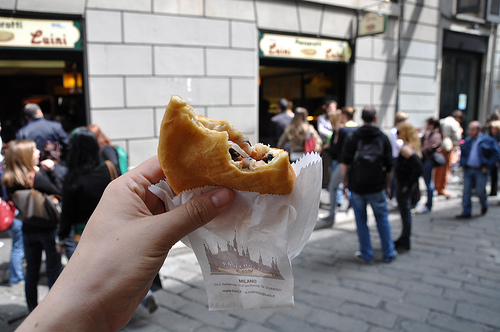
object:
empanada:
[157, 94, 298, 195]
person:
[11, 154, 237, 332]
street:
[0, 203, 500, 332]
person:
[453, 120, 499, 220]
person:
[319, 106, 362, 222]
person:
[54, 126, 122, 262]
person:
[410, 116, 445, 215]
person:
[434, 111, 464, 197]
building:
[0, 0, 500, 188]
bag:
[146, 150, 324, 310]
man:
[338, 105, 398, 264]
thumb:
[146, 187, 235, 241]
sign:
[357, 10, 388, 38]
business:
[258, 34, 358, 188]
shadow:
[372, 0, 423, 129]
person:
[270, 97, 296, 130]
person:
[276, 107, 324, 164]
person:
[15, 102, 71, 163]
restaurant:
[0, 10, 88, 143]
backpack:
[352, 130, 385, 172]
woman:
[391, 123, 425, 255]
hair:
[397, 123, 425, 159]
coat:
[458, 136, 500, 169]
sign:
[257, 32, 354, 65]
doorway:
[260, 57, 349, 189]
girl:
[0, 138, 63, 314]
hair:
[4, 139, 39, 188]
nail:
[211, 188, 232, 209]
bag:
[303, 134, 317, 154]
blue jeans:
[347, 189, 395, 264]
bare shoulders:
[400, 143, 414, 158]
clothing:
[393, 153, 423, 188]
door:
[436, 25, 492, 130]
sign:
[457, 93, 467, 111]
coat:
[13, 115, 69, 160]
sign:
[0, 15, 83, 50]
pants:
[435, 145, 451, 196]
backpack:
[114, 147, 128, 175]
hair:
[63, 127, 102, 195]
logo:
[203, 230, 286, 281]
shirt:
[52, 162, 120, 245]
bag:
[13, 189, 61, 223]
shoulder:
[32, 170, 46, 187]